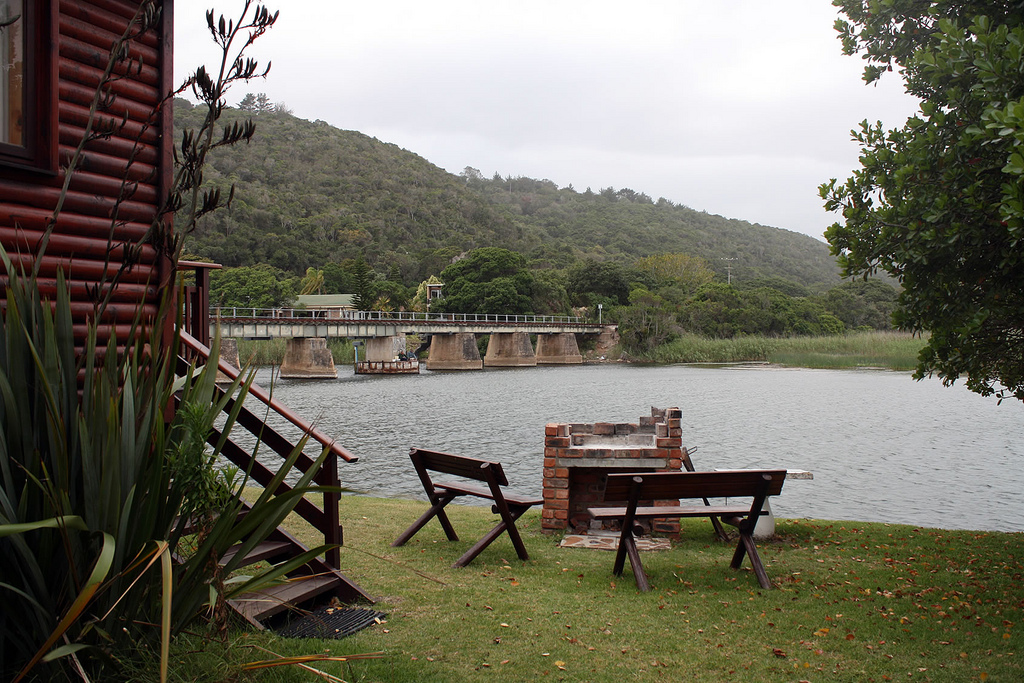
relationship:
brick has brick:
[540, 406, 685, 550] [507, 405, 711, 613]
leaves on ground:
[346, 523, 1015, 676] [388, 573, 939, 677]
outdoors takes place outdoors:
[0, 0, 1024, 683] [198, 275, 989, 680]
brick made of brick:
[540, 406, 685, 550] [540, 406, 685, 550]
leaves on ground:
[784, 567, 972, 653] [504, 574, 1021, 680]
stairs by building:
[178, 325, 365, 636] [25, 33, 302, 572]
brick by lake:
[540, 406, 685, 550] [295, 359, 1004, 504]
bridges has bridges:
[267, 330, 340, 375] [280, 337, 338, 379]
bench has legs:
[392, 446, 543, 567] [459, 510, 498, 574]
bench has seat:
[572, 460, 812, 588] [589, 499, 768, 515]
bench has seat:
[389, 415, 539, 573] [427, 466, 529, 512]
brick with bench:
[540, 406, 685, 550] [588, 470, 790, 593]